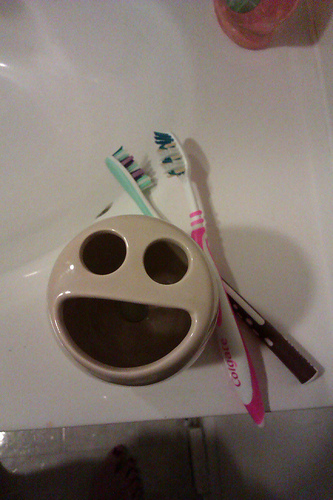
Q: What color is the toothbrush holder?
A: Cream.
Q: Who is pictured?
A: No one.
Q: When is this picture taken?
A: Morning.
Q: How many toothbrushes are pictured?
A: 2.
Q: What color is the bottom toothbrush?
A: Black and green.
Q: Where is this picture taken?
A: Bathroom.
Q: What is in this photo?
A: Two toothbrushes and a holder.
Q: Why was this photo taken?
A: To show the holder and the toothbrushes.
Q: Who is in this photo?
A: No one.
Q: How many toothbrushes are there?
A: Two.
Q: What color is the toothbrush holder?
A: White.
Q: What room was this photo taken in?
A: The bathroom.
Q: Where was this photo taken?
A: Inside a house.